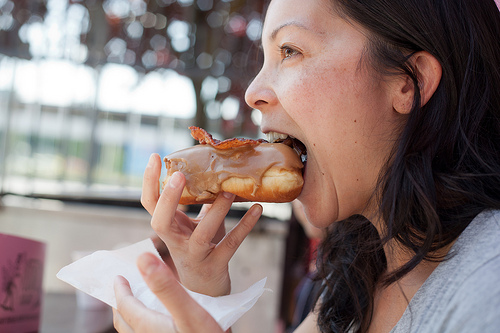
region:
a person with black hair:
[450, 17, 482, 132]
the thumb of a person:
[135, 246, 189, 309]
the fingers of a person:
[142, 157, 246, 251]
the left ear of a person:
[399, 51, 442, 116]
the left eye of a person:
[270, 37, 310, 68]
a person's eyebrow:
[270, 20, 315, 39]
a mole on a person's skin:
[352, 108, 361, 127]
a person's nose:
[241, 68, 281, 109]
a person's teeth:
[259, 128, 289, 140]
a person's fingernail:
[136, 255, 162, 273]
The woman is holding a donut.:
[127, 3, 498, 288]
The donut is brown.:
[156, 126, 302, 206]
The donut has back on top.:
[163, 126, 306, 201]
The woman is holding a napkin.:
[52, 232, 277, 331]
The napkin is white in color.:
[50, 243, 274, 331]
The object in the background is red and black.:
[3, 231, 50, 331]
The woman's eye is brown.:
[276, 42, 303, 60]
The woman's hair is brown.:
[259, 0, 498, 331]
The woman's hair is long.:
[266, 1, 498, 331]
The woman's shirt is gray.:
[273, 0, 498, 331]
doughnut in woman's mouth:
[163, 119, 298, 221]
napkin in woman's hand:
[50, 235, 272, 322]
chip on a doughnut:
[187, 118, 282, 159]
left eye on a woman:
[260, 22, 315, 79]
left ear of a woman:
[388, 43, 447, 128]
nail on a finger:
[166, 166, 186, 189]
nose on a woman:
[238, 75, 279, 112]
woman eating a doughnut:
[38, 4, 493, 331]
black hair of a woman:
[436, 100, 492, 187]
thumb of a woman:
[138, 243, 219, 323]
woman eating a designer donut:
[127, 3, 497, 270]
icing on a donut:
[165, 138, 302, 180]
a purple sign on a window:
[2, 231, 55, 331]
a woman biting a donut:
[140, 0, 498, 250]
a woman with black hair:
[237, 0, 497, 331]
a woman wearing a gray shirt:
[232, 3, 497, 332]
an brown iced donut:
[161, 123, 307, 206]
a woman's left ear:
[392, 40, 448, 135]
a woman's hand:
[84, 244, 248, 331]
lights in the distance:
[4, 3, 261, 210]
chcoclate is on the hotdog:
[165, 141, 285, 178]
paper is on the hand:
[59, 247, 271, 329]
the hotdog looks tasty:
[176, 115, 324, 219]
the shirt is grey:
[430, 234, 495, 331]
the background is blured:
[50, 29, 236, 122]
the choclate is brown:
[170, 133, 288, 183]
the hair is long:
[406, 91, 490, 234]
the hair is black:
[400, 59, 486, 208]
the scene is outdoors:
[4, 1, 476, 327]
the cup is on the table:
[70, 246, 107, 332]